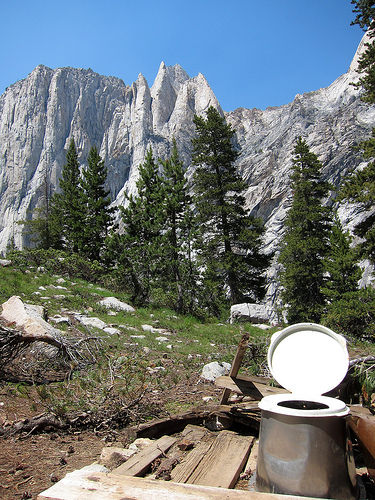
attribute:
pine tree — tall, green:
[186, 100, 270, 332]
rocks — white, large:
[28, 281, 135, 352]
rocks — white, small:
[61, 313, 126, 340]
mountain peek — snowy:
[347, 17, 373, 75]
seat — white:
[258, 392, 350, 418]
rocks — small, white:
[93, 297, 172, 349]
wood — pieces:
[124, 331, 291, 437]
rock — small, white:
[127, 334, 151, 340]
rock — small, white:
[142, 318, 167, 334]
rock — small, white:
[103, 294, 135, 316]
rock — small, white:
[80, 312, 120, 335]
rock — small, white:
[52, 312, 70, 328]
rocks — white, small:
[20, 260, 158, 356]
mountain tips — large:
[124, 62, 215, 105]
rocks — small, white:
[11, 307, 119, 368]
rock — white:
[230, 301, 268, 321]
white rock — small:
[1, 254, 12, 268]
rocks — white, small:
[24, 49, 282, 223]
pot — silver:
[250, 317, 356, 498]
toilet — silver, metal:
[249, 320, 365, 496]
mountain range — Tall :
[1, 19, 373, 320]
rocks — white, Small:
[9, 262, 246, 396]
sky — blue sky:
[0, 0, 374, 110]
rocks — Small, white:
[27, 52, 349, 254]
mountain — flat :
[8, 64, 373, 326]